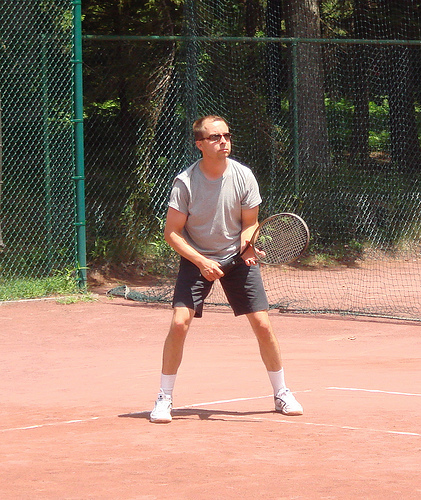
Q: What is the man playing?
A: Tennis.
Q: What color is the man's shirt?
A: Grey.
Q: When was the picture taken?
A: During the day.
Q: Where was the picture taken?
A: At a tennis court.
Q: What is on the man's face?
A: Glasses.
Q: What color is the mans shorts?
A: Black.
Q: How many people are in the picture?
A: One.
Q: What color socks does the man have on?
A: White.